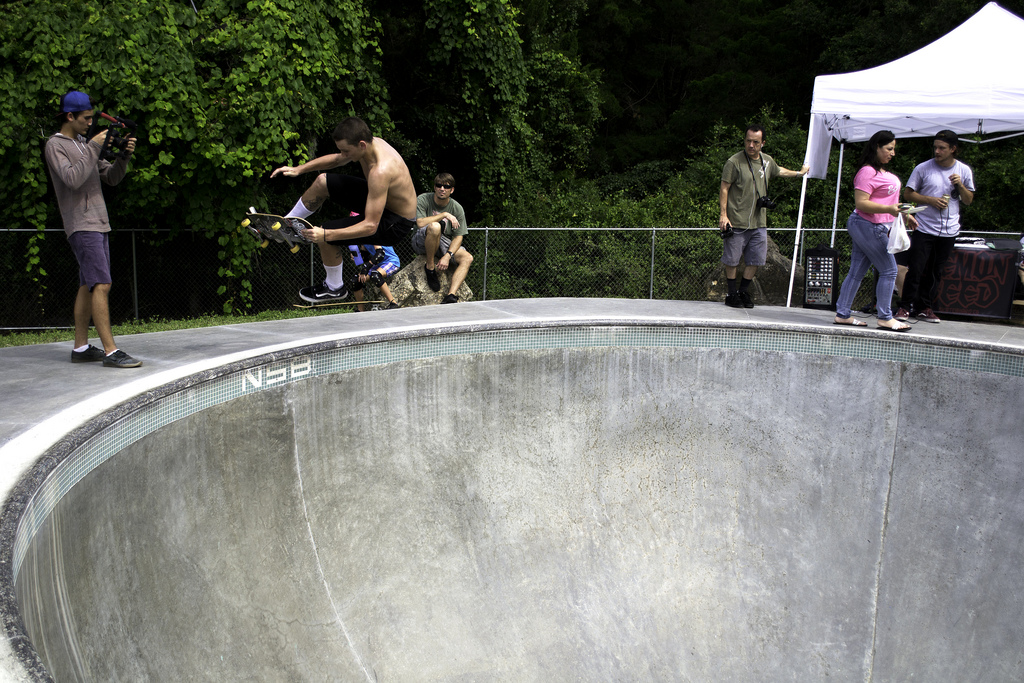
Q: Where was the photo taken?
A: Near the skateboard park.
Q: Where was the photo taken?
A: At a skatepark.